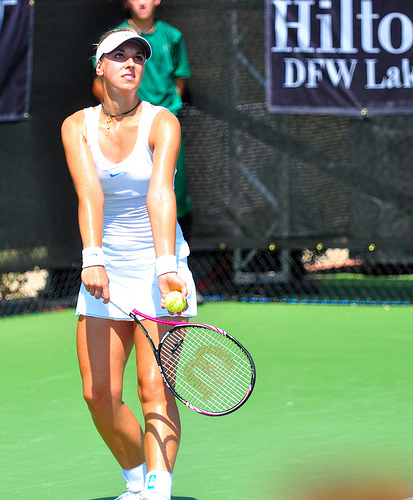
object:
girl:
[60, 26, 199, 499]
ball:
[162, 289, 188, 314]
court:
[0, 302, 412, 499]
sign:
[266, 0, 412, 92]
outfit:
[74, 99, 199, 323]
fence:
[0, 0, 412, 318]